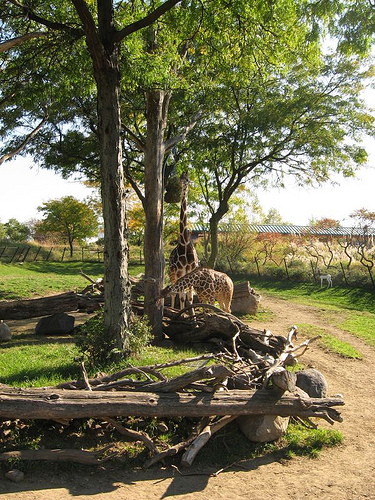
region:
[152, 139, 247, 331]
a giraffe standing under a tree.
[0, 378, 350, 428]
a fallen log on the ground.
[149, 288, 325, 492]
a dried up dead tree.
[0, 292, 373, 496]
a dirt road near dead trees.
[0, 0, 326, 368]
a leafy green tree.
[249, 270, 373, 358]
a patch of green grass.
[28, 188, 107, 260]
a tree filled with leaves.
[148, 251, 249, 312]
a giraffe eating grass.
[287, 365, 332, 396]
a rock on the ground.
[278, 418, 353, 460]
a patch of green grass.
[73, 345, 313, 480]
brown woods on floor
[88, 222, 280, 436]
brown woods on floor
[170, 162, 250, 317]
two giraffes in the field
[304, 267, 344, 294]
a small animal beside the fence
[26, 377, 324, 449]
a log on the ground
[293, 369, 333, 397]
a stone near the log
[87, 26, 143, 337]
the tree trunk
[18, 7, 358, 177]
the tree with green leaves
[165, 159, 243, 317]
the giraffes are spotted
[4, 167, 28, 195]
the sky is blue and clear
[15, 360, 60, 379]
the grass is low and green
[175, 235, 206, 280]
the spots are brown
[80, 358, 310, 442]
brown logs on floor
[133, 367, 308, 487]
brown logs on floor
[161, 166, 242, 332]
Two giraffes standing near a pile of wood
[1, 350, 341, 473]
Dead trees in a pile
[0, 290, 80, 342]
Log on top of two rocks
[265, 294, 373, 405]
A trail worn into the grass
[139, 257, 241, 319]
One giraffe eating the back of a tree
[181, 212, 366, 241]
A building with green roof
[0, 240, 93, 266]
A row of fence posts and wire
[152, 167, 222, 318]
One giraffe standing up tall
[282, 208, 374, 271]
Bendy tree trunks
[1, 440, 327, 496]
Shadows on the ground